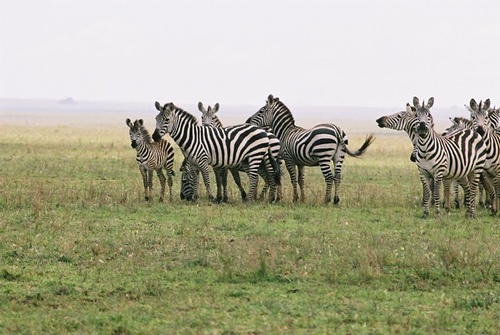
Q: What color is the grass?
A: Green.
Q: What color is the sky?
A: Gray.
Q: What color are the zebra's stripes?
A: Black.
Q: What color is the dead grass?
A: Brown.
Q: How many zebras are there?
A: 9.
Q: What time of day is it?
A: Afternoon.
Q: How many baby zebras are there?
A: One.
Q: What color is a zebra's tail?
A: Black.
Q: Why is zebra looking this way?
A: Facing camera.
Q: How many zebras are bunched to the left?
A: Four.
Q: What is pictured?
A: Group of zebras.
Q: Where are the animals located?
A: Field.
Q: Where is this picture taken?
A: Yellow grasses.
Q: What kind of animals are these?
A: Zebras.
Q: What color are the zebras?
A: Black and white.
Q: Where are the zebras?
A: On the grass.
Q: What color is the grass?
A: Green.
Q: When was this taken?
A: During the daytime.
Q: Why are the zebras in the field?
A: They are grazing the grass.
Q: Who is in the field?
A: A group of zebras.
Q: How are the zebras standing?
A: In a group.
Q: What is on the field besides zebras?
A: Green grass.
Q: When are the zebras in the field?
A: In the day time.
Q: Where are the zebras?
A: In the middle of a field.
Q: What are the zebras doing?
A: Just standing in the field.